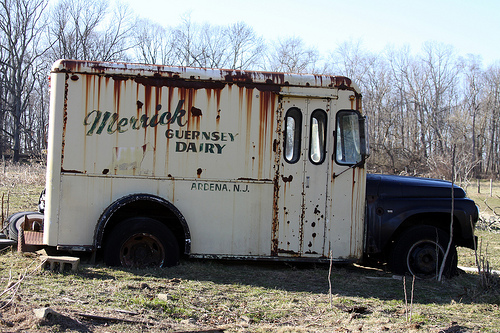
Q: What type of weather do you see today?
A: It is cloudy.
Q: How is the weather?
A: It is cloudy.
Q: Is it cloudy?
A: Yes, it is cloudy.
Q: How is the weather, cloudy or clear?
A: It is cloudy.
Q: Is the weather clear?
A: No, it is cloudy.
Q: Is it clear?
A: No, it is cloudy.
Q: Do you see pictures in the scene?
A: No, there are no pictures.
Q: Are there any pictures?
A: No, there are no pictures.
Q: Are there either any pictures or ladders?
A: No, there are no pictures or ladders.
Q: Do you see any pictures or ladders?
A: No, there are no pictures or ladders.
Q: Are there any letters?
A: Yes, there are letters.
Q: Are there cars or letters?
A: Yes, there are letters.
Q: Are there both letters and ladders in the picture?
A: No, there are letters but no ladders.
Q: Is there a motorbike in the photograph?
A: No, there are no motorcycles.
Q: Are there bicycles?
A: No, there are no bicycles.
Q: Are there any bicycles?
A: No, there are no bicycles.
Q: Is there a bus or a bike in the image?
A: No, there are no bikes or buses.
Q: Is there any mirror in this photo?
A: Yes, there is a mirror.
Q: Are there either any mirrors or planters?
A: Yes, there is a mirror.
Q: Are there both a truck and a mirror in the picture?
A: Yes, there are both a mirror and a truck.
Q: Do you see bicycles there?
A: No, there are no bicycles.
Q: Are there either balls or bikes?
A: No, there are no bikes or balls.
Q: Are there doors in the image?
A: Yes, there is a door.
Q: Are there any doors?
A: Yes, there is a door.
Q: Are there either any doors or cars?
A: Yes, there is a door.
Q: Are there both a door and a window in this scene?
A: Yes, there are both a door and a window.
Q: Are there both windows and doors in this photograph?
A: Yes, there are both a door and a window.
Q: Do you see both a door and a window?
A: Yes, there are both a door and a window.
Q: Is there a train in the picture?
A: No, there are no trains.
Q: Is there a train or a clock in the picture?
A: No, there are no trains or clocks.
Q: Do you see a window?
A: Yes, there are windows.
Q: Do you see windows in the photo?
A: Yes, there are windows.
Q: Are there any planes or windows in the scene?
A: Yes, there are windows.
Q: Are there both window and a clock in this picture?
A: No, there are windows but no clocks.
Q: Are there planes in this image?
A: No, there are no planes.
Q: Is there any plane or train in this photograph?
A: No, there are no airplanes or trains.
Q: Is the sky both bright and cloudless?
A: No, the sky is bright but cloudy.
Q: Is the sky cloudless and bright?
A: No, the sky is bright but cloudy.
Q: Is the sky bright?
A: Yes, the sky is bright.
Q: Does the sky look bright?
A: Yes, the sky is bright.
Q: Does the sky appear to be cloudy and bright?
A: Yes, the sky is cloudy and bright.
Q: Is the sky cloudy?
A: Yes, the sky is cloudy.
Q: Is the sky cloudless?
A: No, the sky is cloudy.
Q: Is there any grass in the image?
A: Yes, there is grass.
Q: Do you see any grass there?
A: Yes, there is grass.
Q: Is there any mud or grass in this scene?
A: Yes, there is grass.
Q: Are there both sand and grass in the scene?
A: No, there is grass but no sand.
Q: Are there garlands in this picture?
A: No, there are no garlands.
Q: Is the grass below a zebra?
A: No, the grass is below the truck.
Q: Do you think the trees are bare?
A: Yes, the trees are bare.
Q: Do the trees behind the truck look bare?
A: Yes, the trees are bare.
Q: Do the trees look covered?
A: No, the trees are bare.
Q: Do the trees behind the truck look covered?
A: No, the trees are bare.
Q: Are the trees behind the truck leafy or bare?
A: The trees are bare.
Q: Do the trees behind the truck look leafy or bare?
A: The trees are bare.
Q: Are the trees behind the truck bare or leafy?
A: The trees are bare.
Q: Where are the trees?
A: The trees are on the grass.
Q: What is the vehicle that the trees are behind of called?
A: The vehicle is a truck.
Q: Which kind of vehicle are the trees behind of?
A: The trees are behind the truck.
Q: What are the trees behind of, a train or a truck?
A: The trees are behind a truck.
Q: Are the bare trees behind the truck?
A: Yes, the trees are behind the truck.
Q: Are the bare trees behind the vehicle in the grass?
A: Yes, the trees are behind the truck.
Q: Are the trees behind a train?
A: No, the trees are behind the truck.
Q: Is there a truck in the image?
A: Yes, there is a truck.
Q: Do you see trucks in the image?
A: Yes, there is a truck.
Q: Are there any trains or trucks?
A: Yes, there is a truck.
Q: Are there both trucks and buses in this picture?
A: No, there is a truck but no buses.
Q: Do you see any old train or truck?
A: Yes, there is an old truck.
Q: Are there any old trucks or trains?
A: Yes, there is an old truck.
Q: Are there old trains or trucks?
A: Yes, there is an old truck.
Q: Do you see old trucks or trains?
A: Yes, there is an old truck.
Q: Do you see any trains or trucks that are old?
A: Yes, the truck is old.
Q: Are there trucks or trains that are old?
A: Yes, the truck is old.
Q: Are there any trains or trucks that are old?
A: Yes, the truck is old.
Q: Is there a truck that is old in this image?
A: Yes, there is an old truck.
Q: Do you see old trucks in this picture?
A: Yes, there is an old truck.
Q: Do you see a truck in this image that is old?
A: Yes, there is a truck that is old.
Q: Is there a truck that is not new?
A: Yes, there is a old truck.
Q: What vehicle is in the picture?
A: The vehicle is a truck.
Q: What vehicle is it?
A: The vehicle is a truck.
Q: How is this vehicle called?
A: This is a truck.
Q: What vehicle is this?
A: This is a truck.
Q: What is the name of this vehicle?
A: This is a truck.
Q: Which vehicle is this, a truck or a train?
A: This is a truck.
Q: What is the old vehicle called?
A: The vehicle is a truck.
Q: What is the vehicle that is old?
A: The vehicle is a truck.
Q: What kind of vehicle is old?
A: The vehicle is a truck.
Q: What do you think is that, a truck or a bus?
A: That is a truck.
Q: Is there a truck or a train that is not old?
A: No, there is a truck but it is old.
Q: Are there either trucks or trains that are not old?
A: No, there is a truck but it is old.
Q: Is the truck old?
A: Yes, the truck is old.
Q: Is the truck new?
A: No, the truck is old.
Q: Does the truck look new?
A: No, the truck is old.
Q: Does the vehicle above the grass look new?
A: No, the truck is old.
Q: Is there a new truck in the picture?
A: No, there is a truck but it is old.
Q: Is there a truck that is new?
A: No, there is a truck but it is old.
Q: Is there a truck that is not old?
A: No, there is a truck but it is old.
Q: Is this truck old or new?
A: The truck is old.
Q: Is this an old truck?
A: Yes, this is an old truck.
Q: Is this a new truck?
A: No, this is an old truck.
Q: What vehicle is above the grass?
A: The vehicle is a truck.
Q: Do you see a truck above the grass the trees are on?
A: Yes, there is a truck above the grass.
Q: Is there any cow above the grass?
A: No, there is a truck above the grass.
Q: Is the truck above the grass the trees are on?
A: Yes, the truck is above the grass.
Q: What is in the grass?
A: The truck is in the grass.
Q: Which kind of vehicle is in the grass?
A: The vehicle is a truck.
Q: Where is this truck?
A: The truck is in the grass.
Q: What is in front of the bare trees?
A: The truck is in front of the trees.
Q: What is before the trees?
A: The truck is in front of the trees.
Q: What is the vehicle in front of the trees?
A: The vehicle is a truck.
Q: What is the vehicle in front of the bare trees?
A: The vehicle is a truck.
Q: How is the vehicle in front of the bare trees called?
A: The vehicle is a truck.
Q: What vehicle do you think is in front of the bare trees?
A: The vehicle is a truck.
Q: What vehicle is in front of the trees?
A: The vehicle is a truck.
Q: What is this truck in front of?
A: The truck is in front of the trees.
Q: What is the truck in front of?
A: The truck is in front of the trees.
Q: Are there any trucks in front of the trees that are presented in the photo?
A: Yes, there is a truck in front of the trees.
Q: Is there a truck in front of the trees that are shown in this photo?
A: Yes, there is a truck in front of the trees.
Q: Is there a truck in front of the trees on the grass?
A: Yes, there is a truck in front of the trees.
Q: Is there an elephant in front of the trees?
A: No, there is a truck in front of the trees.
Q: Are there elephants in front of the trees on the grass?
A: No, there is a truck in front of the trees.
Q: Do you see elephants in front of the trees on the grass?
A: No, there is a truck in front of the trees.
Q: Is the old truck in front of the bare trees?
A: Yes, the truck is in front of the trees.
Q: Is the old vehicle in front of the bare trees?
A: Yes, the truck is in front of the trees.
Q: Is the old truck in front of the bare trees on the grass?
A: Yes, the truck is in front of the trees.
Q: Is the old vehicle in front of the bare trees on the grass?
A: Yes, the truck is in front of the trees.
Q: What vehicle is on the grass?
A: The vehicle is a truck.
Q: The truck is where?
A: The truck is on the grass.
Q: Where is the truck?
A: The truck is on the grass.